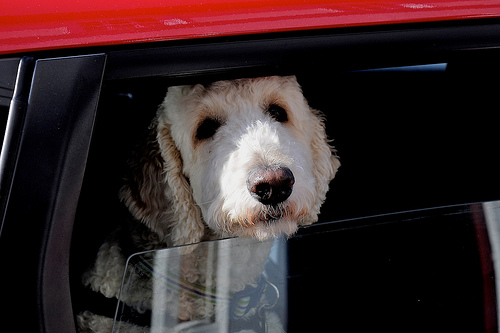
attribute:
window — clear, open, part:
[107, 197, 500, 331]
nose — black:
[247, 167, 293, 204]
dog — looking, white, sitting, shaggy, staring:
[80, 74, 341, 332]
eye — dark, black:
[191, 113, 223, 141]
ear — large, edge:
[121, 111, 207, 253]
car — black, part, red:
[2, 1, 499, 327]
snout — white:
[181, 142, 376, 258]